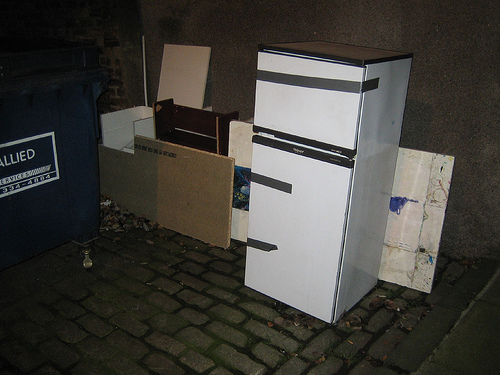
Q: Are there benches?
A: No, there are no benches.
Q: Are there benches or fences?
A: No, there are no benches or fences.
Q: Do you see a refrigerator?
A: Yes, there is a refrigerator.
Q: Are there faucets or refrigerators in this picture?
A: Yes, there is a refrigerator.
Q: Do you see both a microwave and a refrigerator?
A: No, there is a refrigerator but no microwaves.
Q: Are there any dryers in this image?
A: No, there are no dryers.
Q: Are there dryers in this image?
A: No, there are no dryers.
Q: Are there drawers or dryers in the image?
A: No, there are no dryers or drawers.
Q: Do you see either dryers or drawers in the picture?
A: No, there are no dryers or drawers.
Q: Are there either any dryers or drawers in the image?
A: No, there are no dryers or drawers.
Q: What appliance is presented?
A: The appliance is a refrigerator.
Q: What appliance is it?
A: The appliance is a refrigerator.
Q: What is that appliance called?
A: This is a refrigerator.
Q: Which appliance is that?
A: This is a refrigerator.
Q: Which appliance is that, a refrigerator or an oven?
A: This is a refrigerator.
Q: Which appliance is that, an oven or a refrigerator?
A: This is a refrigerator.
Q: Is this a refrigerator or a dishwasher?
A: This is a refrigerator.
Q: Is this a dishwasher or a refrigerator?
A: This is a refrigerator.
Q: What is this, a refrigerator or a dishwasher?
A: This is a refrigerator.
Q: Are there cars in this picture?
A: No, there are no cars.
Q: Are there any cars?
A: No, there are no cars.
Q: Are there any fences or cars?
A: No, there are no cars or fences.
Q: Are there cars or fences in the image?
A: No, there are no cars or fences.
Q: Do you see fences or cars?
A: No, there are no cars or fences.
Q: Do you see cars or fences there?
A: No, there are no cars or fences.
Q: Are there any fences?
A: No, there are no fences.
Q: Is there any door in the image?
A: Yes, there is a door.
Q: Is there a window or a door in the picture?
A: Yes, there is a door.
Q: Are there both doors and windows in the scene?
A: No, there is a door but no windows.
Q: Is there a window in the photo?
A: No, there are no windows.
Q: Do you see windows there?
A: No, there are no windows.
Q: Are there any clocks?
A: No, there are no clocks.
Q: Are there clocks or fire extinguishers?
A: No, there are no clocks or fire extinguishers.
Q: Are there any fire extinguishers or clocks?
A: No, there are no clocks or fire extinguishers.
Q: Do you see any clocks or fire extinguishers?
A: No, there are no clocks or fire extinguishers.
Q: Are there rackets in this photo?
A: No, there are no rackets.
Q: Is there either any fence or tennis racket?
A: No, there are no rackets or fences.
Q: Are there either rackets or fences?
A: No, there are no rackets or fences.